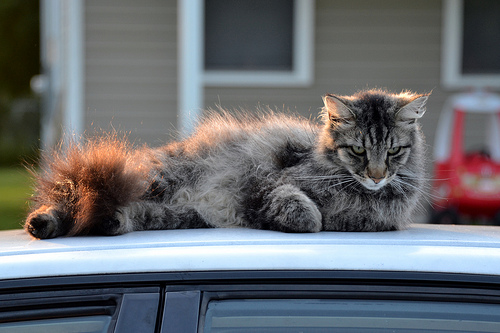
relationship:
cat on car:
[46, 109, 452, 239] [414, 247, 479, 280]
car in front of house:
[414, 247, 479, 280] [336, 11, 390, 31]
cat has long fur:
[46, 109, 452, 239] [89, 105, 303, 153]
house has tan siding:
[336, 11, 390, 31] [98, 10, 158, 29]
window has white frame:
[170, 5, 341, 105] [261, 60, 327, 86]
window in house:
[170, 5, 341, 105] [336, 11, 390, 31]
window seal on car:
[201, 275, 315, 291] [414, 247, 479, 280]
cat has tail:
[46, 109, 452, 239] [55, 143, 129, 198]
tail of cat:
[55, 143, 129, 198] [46, 109, 452, 239]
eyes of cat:
[349, 136, 408, 155] [46, 109, 452, 239]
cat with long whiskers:
[46, 109, 452, 239] [399, 173, 439, 208]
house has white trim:
[336, 11, 390, 31] [171, 37, 201, 120]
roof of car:
[16, 228, 164, 276] [414, 247, 479, 280]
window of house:
[170, 5, 341, 105] [336, 11, 390, 31]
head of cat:
[323, 88, 417, 188] [46, 109, 452, 239]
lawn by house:
[7, 166, 29, 208] [336, 11, 390, 31]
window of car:
[329, 309, 438, 325] [414, 247, 479, 280]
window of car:
[170, 5, 341, 105] [414, 247, 479, 280]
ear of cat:
[388, 102, 445, 125] [46, 109, 452, 239]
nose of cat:
[370, 162, 401, 184] [46, 109, 452, 239]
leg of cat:
[97, 193, 183, 225] [46, 109, 452, 239]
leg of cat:
[9, 187, 80, 226] [46, 109, 452, 239]